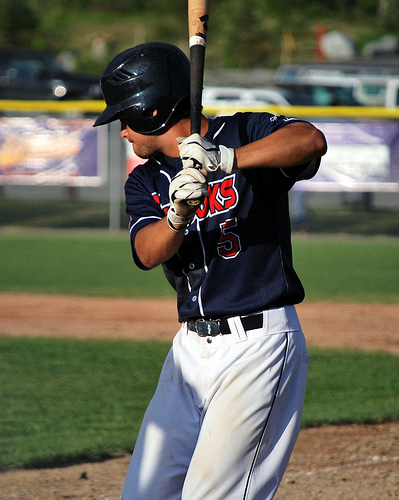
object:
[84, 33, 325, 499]
batter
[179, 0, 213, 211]
bat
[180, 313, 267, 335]
belt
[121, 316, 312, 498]
pants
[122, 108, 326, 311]
shirt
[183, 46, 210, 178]
handle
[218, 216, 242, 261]
number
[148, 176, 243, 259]
lettering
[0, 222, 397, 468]
grass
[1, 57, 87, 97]
cars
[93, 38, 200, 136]
helmet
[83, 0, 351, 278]
batting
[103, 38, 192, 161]
head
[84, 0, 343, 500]
baseball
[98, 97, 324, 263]
skin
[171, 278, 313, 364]
waist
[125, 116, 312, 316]
trim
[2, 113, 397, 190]
advertising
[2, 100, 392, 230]
wall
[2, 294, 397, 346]
clay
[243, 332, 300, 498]
trim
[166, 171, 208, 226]
glove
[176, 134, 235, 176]
glove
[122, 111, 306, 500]
uniform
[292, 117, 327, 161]
elbow